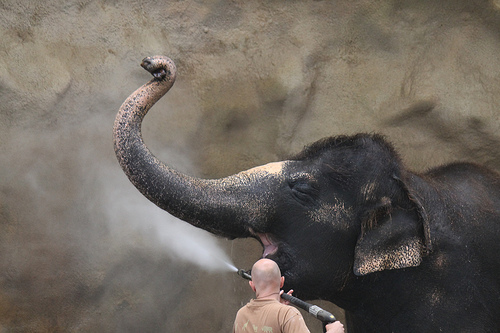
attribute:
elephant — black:
[112, 54, 497, 332]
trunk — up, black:
[111, 50, 290, 236]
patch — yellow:
[204, 158, 302, 186]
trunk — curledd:
[110, 45, 272, 242]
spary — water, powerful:
[76, 133, 246, 280]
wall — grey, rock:
[8, 10, 485, 316]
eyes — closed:
[288, 172, 326, 205]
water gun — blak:
[232, 263, 340, 323]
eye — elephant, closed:
[281, 175, 326, 204]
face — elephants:
[242, 153, 353, 296]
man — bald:
[231, 255, 341, 328]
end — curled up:
[107, 51, 183, 171]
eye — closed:
[289, 179, 325, 205]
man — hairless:
[231, 253, 348, 331]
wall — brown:
[0, 0, 497, 330]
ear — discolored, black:
[345, 168, 435, 279]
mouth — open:
[236, 222, 286, 276]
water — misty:
[76, 82, 238, 277]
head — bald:
[248, 257, 286, 302]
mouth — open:
[245, 224, 281, 275]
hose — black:
[238, 270, 338, 325]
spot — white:
[243, 159, 297, 179]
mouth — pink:
[244, 226, 276, 271]